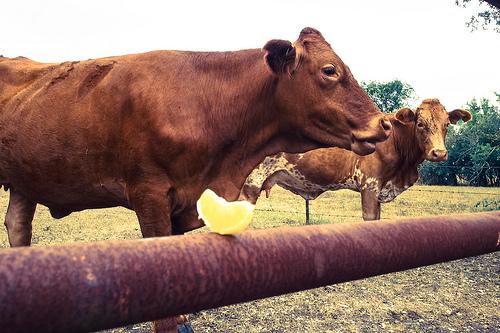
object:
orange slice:
[196, 189, 255, 235]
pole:
[1, 209, 500, 332]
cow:
[1, 27, 394, 332]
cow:
[237, 98, 472, 222]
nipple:
[265, 186, 272, 198]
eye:
[321, 65, 338, 77]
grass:
[1, 184, 500, 332]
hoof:
[175, 321, 194, 332]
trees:
[354, 80, 500, 187]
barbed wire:
[407, 188, 499, 197]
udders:
[261, 175, 279, 197]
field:
[1, 0, 500, 333]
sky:
[1, 0, 500, 132]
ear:
[261, 37, 302, 75]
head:
[263, 26, 393, 156]